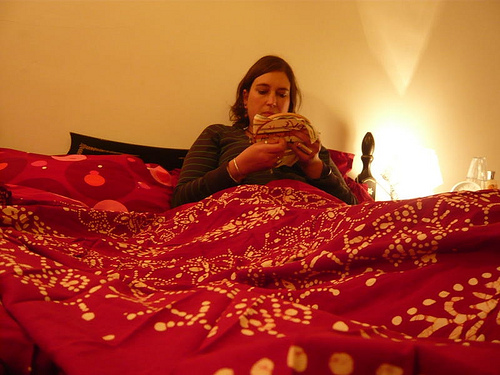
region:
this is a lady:
[189, 50, 336, 195]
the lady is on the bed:
[182, 46, 319, 201]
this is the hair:
[257, 55, 273, 67]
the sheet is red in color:
[156, 195, 389, 360]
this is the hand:
[233, 136, 281, 168]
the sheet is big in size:
[86, 205, 448, 373]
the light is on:
[366, 146, 433, 200]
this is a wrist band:
[231, 152, 243, 175]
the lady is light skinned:
[271, 75, 283, 83]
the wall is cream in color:
[85, 37, 183, 122]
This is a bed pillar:
[351, 130, 414, 235]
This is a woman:
[164, 34, 359, 240]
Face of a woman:
[255, 70, 286, 116]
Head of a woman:
[224, 45, 306, 125]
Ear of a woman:
[231, 80, 255, 115]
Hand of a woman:
[158, 123, 284, 211]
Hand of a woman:
[291, 120, 360, 217]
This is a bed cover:
[23, 153, 498, 368]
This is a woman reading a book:
[0, 38, 488, 365]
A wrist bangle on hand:
[226, 143, 248, 198]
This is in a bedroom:
[24, 18, 442, 364]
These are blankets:
[27, 184, 459, 361]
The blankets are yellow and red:
[91, 218, 398, 374]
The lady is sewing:
[219, 96, 416, 185]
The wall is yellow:
[53, 16, 179, 122]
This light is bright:
[309, 34, 449, 142]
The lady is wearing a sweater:
[182, 112, 396, 227]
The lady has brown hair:
[239, 49, 323, 145]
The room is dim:
[21, 74, 458, 369]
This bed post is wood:
[347, 117, 385, 202]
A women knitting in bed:
[169, 50, 364, 209]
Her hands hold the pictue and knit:
[250, 110, 324, 174]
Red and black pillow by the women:
[1, 129, 177, 212]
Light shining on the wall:
[381, 2, 443, 194]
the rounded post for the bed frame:
[354, 127, 375, 204]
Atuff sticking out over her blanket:
[458, 152, 498, 196]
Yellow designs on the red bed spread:
[90, 215, 497, 374]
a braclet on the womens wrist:
[228, 152, 247, 178]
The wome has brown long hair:
[229, 56, 304, 121]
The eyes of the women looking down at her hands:
[250, 78, 289, 101]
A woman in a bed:
[0, 1, 499, 373]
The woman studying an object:
[172, 53, 357, 213]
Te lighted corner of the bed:
[356, 94, 497, 200]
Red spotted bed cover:
[0, 151, 499, 373]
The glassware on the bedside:
[454, 155, 494, 192]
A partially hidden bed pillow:
[65, 133, 190, 171]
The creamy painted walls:
[0, 0, 498, 202]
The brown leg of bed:
[354, 130, 376, 199]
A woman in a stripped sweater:
[172, 54, 356, 205]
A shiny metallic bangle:
[231, 157, 243, 179]